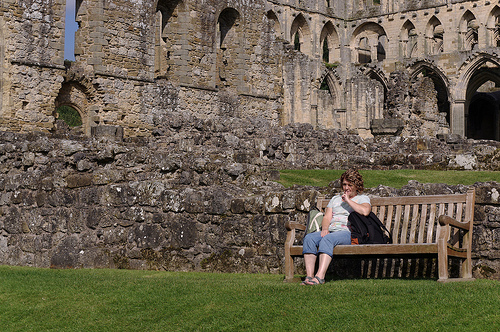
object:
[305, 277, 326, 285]
feet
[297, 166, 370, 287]
lady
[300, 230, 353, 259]
capris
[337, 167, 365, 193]
hair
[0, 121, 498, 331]
no snow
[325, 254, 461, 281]
shadows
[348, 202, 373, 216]
arm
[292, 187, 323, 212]
rocks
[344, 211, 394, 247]
bag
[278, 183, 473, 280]
wooden bench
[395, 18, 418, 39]
arch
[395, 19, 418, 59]
window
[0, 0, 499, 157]
building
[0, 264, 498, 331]
grass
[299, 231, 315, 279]
leg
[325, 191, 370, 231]
shirt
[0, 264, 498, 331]
lawn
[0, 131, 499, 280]
wall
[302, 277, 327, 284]
sandals